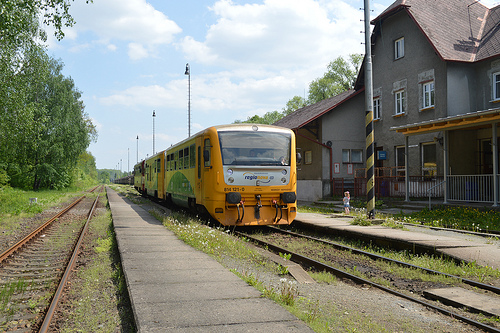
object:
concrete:
[103, 182, 318, 333]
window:
[216, 129, 293, 167]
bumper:
[240, 201, 245, 222]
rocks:
[408, 283, 413, 286]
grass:
[109, 182, 386, 332]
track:
[0, 183, 98, 263]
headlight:
[281, 169, 287, 175]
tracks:
[235, 224, 500, 331]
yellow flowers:
[449, 209, 451, 210]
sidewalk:
[103, 182, 315, 331]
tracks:
[37, 192, 102, 332]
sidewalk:
[295, 209, 499, 273]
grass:
[49, 192, 129, 332]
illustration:
[166, 171, 195, 196]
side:
[133, 126, 226, 226]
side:
[319, 94, 367, 198]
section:
[104, 185, 311, 333]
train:
[131, 123, 300, 228]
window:
[393, 87, 406, 115]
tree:
[0, 44, 99, 190]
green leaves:
[58, 39, 60, 42]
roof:
[272, 88, 364, 129]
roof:
[405, 0, 483, 61]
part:
[401, 0, 500, 63]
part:
[350, 53, 368, 92]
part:
[388, 108, 500, 136]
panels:
[131, 298, 300, 328]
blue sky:
[8, 0, 419, 173]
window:
[204, 139, 211, 167]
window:
[197, 145, 201, 179]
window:
[189, 144, 196, 167]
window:
[157, 159, 160, 172]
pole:
[188, 62, 192, 137]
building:
[349, 0, 500, 201]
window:
[370, 93, 383, 120]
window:
[341, 149, 364, 163]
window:
[419, 79, 437, 111]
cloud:
[0, 0, 396, 169]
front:
[213, 123, 298, 226]